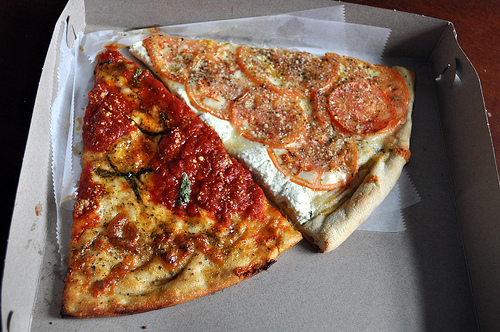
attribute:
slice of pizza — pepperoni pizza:
[132, 31, 413, 251]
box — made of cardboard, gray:
[2, 3, 499, 326]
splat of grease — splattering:
[25, 221, 64, 307]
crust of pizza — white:
[302, 63, 415, 254]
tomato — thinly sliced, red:
[329, 80, 395, 143]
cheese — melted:
[65, 50, 282, 293]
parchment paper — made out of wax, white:
[51, 17, 422, 278]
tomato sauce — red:
[76, 83, 267, 223]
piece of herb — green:
[176, 170, 193, 207]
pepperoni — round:
[230, 89, 303, 143]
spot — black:
[98, 59, 114, 68]